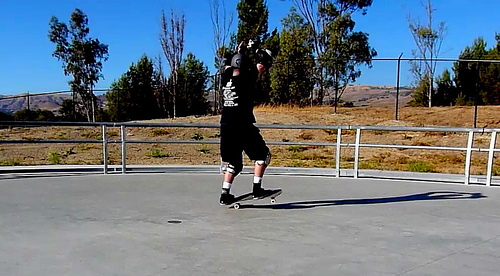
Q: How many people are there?
A: One.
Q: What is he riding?
A: Skateboard.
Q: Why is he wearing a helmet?
A: For safety.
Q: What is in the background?
A: A fence.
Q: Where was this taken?
A: Skate Park.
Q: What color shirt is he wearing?
A: Black.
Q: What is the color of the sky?
A: Blue.